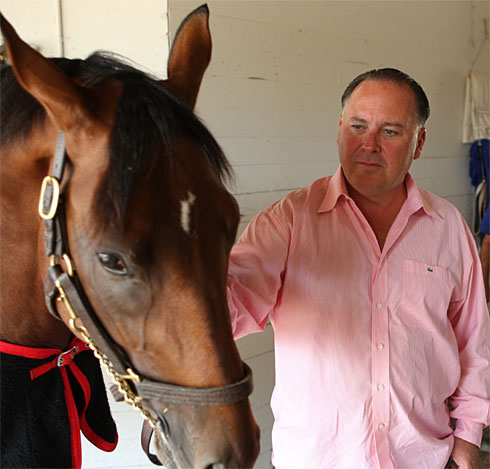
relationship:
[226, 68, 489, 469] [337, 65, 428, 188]
person has a head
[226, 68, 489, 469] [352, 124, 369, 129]
person has an eye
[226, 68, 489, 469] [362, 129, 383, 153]
person has a nose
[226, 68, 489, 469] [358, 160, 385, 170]
person has a mouth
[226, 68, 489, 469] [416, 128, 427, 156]
person has an ear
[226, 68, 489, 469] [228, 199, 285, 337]
person has an arm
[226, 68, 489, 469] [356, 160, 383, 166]
person has a lip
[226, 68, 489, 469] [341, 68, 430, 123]
person has hair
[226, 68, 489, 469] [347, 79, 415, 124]
person has a forehead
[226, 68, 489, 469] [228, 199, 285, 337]
person has a arm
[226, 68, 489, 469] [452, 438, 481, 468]
person has a hand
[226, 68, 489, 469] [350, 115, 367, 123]
person has an eyebrow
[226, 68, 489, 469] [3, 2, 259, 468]
person next to a horse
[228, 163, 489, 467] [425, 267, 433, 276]
shirt has a logo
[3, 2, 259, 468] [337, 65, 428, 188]
horse has a head